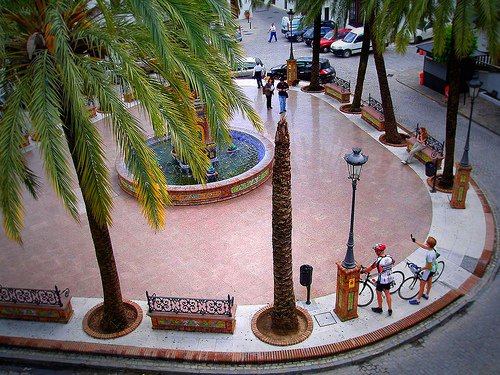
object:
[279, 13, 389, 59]
park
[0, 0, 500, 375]
city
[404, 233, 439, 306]
bicyclists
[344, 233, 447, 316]
park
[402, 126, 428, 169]
woman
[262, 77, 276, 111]
people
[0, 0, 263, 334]
palm tree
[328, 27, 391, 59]
cars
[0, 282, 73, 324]
benches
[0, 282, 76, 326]
of the park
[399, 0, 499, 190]
that is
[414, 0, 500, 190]
tree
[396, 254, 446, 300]
bicycles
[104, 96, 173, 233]
colorful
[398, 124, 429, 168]
woman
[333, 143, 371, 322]
to lamp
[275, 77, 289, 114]
people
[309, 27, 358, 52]
cars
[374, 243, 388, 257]
helmet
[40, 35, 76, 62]
leaves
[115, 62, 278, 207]
fountain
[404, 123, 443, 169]
benches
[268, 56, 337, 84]
car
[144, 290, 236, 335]
bench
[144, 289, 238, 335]
fountain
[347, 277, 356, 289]
sign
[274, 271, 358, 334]
tree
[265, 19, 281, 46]
man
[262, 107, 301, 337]
no fronds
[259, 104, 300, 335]
tree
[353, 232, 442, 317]
two bikes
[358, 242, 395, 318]
bicyclists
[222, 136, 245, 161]
water